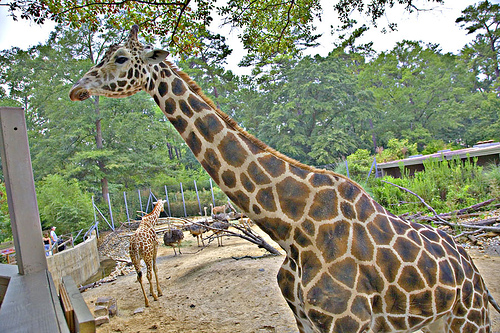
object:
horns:
[123, 22, 139, 42]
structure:
[372, 140, 494, 177]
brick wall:
[41, 227, 99, 298]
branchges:
[368, 150, 498, 209]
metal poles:
[89, 173, 224, 230]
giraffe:
[68, 17, 498, 331]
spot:
[313, 217, 350, 262]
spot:
[351, 222, 376, 260]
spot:
[383, 282, 408, 314]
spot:
[216, 130, 248, 167]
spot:
[419, 232, 446, 259]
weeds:
[384, 151, 486, 215]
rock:
[147, 316, 165, 330]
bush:
[377, 176, 422, 211]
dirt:
[14, 219, 496, 331]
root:
[231, 257, 258, 264]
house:
[366, 145, 497, 193]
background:
[3, 1, 484, 240]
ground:
[90, 216, 483, 330]